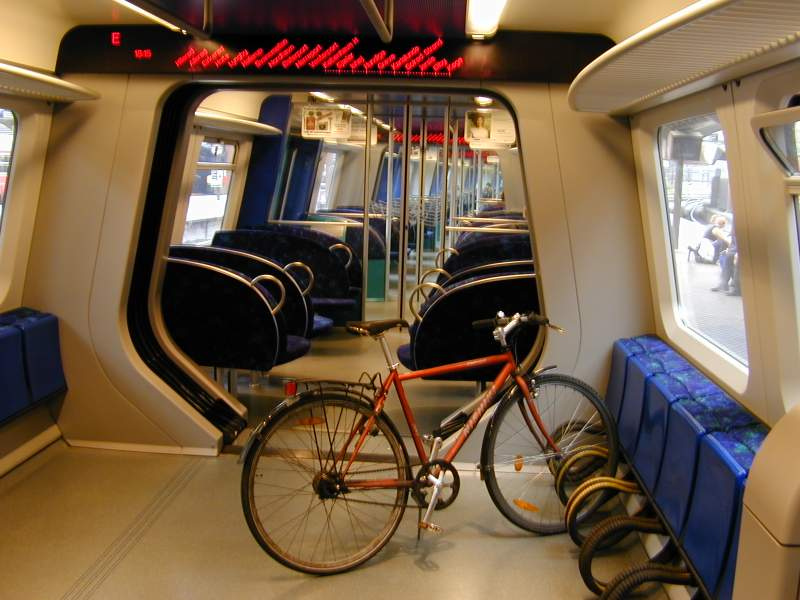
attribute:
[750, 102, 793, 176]
window — partial open